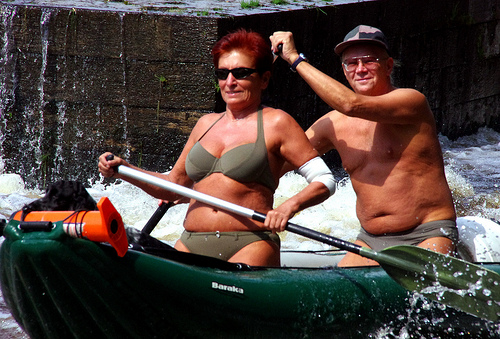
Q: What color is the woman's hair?
A: Red.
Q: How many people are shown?
A: Two.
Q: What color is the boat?
A: Green.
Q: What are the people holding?
A: Paddles.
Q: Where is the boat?
A: In the water.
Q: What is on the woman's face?
A: Sunglasses.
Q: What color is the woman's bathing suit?
A: Green.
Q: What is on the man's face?
A: Glasses.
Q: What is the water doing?
A: Splashing.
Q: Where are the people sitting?
A: In a boat.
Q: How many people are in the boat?
A: 2.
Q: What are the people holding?
A: Oars.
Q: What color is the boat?
A: Green.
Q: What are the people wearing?
A: Swimsuits.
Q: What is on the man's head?
A: A hat.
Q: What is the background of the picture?
A: A stone wall.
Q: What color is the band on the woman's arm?
A: White.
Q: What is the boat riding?
A: Rapids.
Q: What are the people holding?
A: Paddles.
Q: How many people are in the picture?
A: 2.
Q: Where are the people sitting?
A: In a boat.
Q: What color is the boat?
A: Green.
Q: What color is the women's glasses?
A: Black.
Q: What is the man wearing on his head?
A: A hat.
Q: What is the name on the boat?
A: Baraka.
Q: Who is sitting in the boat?
A: A man and women.